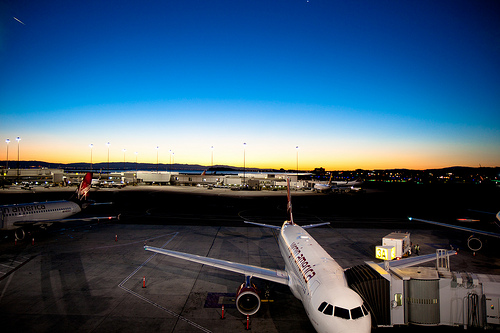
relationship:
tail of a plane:
[239, 175, 334, 231] [126, 176, 482, 323]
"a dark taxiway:
[348, 166, 496, 203] [380, 173, 495, 206]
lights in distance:
[7, 143, 319, 169] [1, 142, 306, 187]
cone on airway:
[12, 231, 266, 329] [1, 149, 497, 168]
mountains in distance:
[0, 160, 497, 170] [1, 142, 306, 187]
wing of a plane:
[76, 170, 334, 232] [126, 176, 482, 323]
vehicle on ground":
[1, 183, 379, 198] [2, 166, 379, 193]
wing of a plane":
[76, 170, 334, 232] [239, 175, 334, 231]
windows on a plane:
[1, 205, 82, 228] [126, 176, 482, 323]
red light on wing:
[55, 213, 122, 227] [76, 170, 334, 232]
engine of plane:
[219, 270, 267, 317] [126, 176, 482, 323]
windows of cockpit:
[1, 205, 82, 228] [298, 289, 383, 333]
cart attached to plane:
[344, 254, 498, 332] [126, 176, 482, 323]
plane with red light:
[126, 176, 482, 323] [104, 215, 113, 222]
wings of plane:
[133, 244, 460, 286] [126, 176, 482, 323]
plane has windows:
[126, 176, 482, 323] [1, 205, 82, 228]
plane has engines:
[126, 176, 482, 323] [219, 270, 267, 317]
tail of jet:
[239, 175, 334, 231] [139, 186, 482, 330]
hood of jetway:
[278, 229, 381, 332] [371, 261, 483, 330]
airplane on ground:
[126, 176, 482, 323] [12, 200, 462, 330]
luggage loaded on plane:
[371, 231, 417, 256] [141, 174, 465, 331]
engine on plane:
[126, 176, 482, 323] [141, 174, 465, 331]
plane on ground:
[126, 176, 482, 323] [2, 185, 482, 331]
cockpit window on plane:
[298, 289, 383, 333] [141, 174, 465, 331]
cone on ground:
[136, 269, 148, 293] [2, 185, 482, 331]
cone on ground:
[220, 304, 229, 320] [2, 185, 482, 331]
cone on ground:
[242, 311, 252, 331] [2, 185, 482, 331]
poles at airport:
[1, 142, 306, 187] [0, 133, 324, 196]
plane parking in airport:
[126, 176, 482, 323] [0, 133, 324, 196]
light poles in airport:
[1, 142, 306, 187] [0, 133, 324, 196]